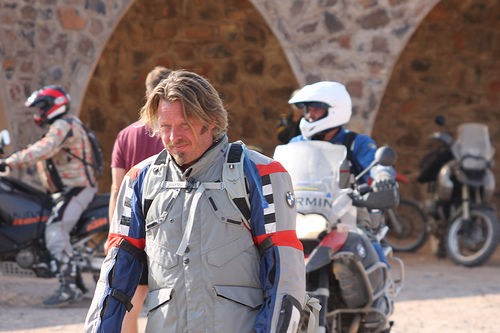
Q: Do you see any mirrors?
A: Yes, there is a mirror.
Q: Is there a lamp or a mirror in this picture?
A: Yes, there is a mirror.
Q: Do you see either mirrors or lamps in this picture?
A: Yes, there is a mirror.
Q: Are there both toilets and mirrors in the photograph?
A: No, there is a mirror but no toilets.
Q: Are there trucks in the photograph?
A: No, there are no trucks.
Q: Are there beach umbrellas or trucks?
A: No, there are no trucks or beach umbrellas.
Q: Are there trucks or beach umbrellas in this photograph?
A: No, there are no trucks or beach umbrellas.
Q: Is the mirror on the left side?
A: No, the mirror is on the right of the image.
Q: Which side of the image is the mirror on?
A: The mirror is on the right of the image.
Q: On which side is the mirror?
A: The mirror is on the right of the image.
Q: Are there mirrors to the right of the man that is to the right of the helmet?
A: Yes, there is a mirror to the right of the man.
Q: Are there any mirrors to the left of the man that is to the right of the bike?
A: No, the mirror is to the right of the man.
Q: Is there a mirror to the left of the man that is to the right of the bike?
A: No, the mirror is to the right of the man.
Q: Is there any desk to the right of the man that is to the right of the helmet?
A: No, there is a mirror to the right of the man.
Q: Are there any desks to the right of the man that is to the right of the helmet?
A: No, there is a mirror to the right of the man.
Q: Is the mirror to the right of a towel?
A: No, the mirror is to the right of the man.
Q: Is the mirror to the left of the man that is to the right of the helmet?
A: No, the mirror is to the right of the man.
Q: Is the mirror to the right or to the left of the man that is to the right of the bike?
A: The mirror is to the right of the man.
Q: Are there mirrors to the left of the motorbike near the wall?
A: Yes, there is a mirror to the left of the motorcycle.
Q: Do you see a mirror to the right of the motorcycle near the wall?
A: No, the mirror is to the left of the motorbike.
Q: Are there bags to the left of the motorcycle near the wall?
A: No, there is a mirror to the left of the motorcycle.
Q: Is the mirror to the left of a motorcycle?
A: Yes, the mirror is to the left of a motorcycle.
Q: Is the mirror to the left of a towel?
A: No, the mirror is to the left of a motorcycle.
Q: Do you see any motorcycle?
A: Yes, there is a motorcycle.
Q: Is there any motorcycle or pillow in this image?
A: Yes, there is a motorcycle.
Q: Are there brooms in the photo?
A: No, there are no brooms.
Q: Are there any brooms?
A: No, there are no brooms.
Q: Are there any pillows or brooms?
A: No, there are no brooms or pillows.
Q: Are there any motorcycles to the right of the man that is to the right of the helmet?
A: Yes, there is a motorcycle to the right of the man.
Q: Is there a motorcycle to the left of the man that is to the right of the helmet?
A: No, the motorcycle is to the right of the man.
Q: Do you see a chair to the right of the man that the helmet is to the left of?
A: No, there is a motorcycle to the right of the man.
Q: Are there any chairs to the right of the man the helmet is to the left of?
A: No, there is a motorcycle to the right of the man.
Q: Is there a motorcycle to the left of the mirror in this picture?
A: No, the motorcycle is to the right of the mirror.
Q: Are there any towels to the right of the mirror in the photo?
A: No, there is a motorcycle to the right of the mirror.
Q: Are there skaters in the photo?
A: No, there are no skaters.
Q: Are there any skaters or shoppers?
A: No, there are no skaters or shoppers.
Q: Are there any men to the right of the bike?
A: Yes, there is a man to the right of the bike.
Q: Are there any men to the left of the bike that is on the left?
A: No, the man is to the right of the bike.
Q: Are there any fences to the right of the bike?
A: No, there is a man to the right of the bike.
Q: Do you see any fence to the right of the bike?
A: No, there is a man to the right of the bike.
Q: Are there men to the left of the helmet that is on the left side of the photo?
A: No, the man is to the right of the helmet.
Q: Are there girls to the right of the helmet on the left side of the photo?
A: No, there is a man to the right of the helmet.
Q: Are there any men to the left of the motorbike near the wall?
A: Yes, there is a man to the left of the motorcycle.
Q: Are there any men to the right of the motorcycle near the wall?
A: No, the man is to the left of the motorbike.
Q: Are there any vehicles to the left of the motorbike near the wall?
A: No, there is a man to the left of the motorbike.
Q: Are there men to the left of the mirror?
A: Yes, there is a man to the left of the mirror.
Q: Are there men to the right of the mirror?
A: No, the man is to the left of the mirror.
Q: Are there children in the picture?
A: No, there are no children.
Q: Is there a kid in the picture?
A: No, there are no children.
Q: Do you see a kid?
A: No, there are no children.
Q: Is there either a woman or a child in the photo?
A: No, there are no children or women.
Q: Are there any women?
A: No, there are no women.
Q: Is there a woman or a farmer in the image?
A: No, there are no women or farmers.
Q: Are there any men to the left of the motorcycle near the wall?
A: Yes, there is a man to the left of the motorbike.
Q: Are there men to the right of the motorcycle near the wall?
A: No, the man is to the left of the motorbike.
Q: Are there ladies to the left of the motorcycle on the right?
A: No, there is a man to the left of the motorbike.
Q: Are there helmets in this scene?
A: Yes, there is a helmet.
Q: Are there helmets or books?
A: Yes, there is a helmet.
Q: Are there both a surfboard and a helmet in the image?
A: No, there is a helmet but no surfboards.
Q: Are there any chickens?
A: No, there are no chickens.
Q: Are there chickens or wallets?
A: No, there are no chickens or wallets.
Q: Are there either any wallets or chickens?
A: No, there are no chickens or wallets.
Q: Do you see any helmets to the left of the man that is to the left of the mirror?
A: Yes, there is a helmet to the left of the man.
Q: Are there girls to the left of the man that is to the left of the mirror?
A: No, there is a helmet to the left of the man.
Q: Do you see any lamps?
A: No, there are no lamps.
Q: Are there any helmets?
A: Yes, there is a helmet.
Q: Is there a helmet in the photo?
A: Yes, there is a helmet.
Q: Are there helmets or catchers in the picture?
A: Yes, there is a helmet.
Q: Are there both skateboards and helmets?
A: No, there is a helmet but no skateboards.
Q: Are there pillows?
A: No, there are no pillows.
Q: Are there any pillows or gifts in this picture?
A: No, there are no pillows or gifts.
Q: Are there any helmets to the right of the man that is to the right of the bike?
A: Yes, there is a helmet to the right of the man.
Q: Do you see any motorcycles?
A: Yes, there is a motorcycle.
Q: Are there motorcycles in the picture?
A: Yes, there is a motorcycle.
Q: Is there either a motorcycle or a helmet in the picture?
A: Yes, there is a motorcycle.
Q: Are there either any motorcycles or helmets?
A: Yes, there is a motorcycle.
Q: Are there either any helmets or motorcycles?
A: Yes, there is a motorcycle.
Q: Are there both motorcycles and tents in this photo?
A: No, there is a motorcycle but no tents.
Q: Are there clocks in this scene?
A: No, there are no clocks.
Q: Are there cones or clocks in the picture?
A: No, there are no clocks or cones.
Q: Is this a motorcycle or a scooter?
A: This is a motorcycle.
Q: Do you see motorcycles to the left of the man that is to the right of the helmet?
A: No, the motorcycle is to the right of the man.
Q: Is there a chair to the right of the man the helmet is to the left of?
A: No, there is a motorcycle to the right of the man.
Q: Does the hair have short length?
A: Yes, the hair is short.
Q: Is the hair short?
A: Yes, the hair is short.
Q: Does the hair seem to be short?
A: Yes, the hair is short.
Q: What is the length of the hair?
A: The hair is short.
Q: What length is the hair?
A: The hair is short.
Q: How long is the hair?
A: The hair is short.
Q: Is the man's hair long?
A: No, the hair is short.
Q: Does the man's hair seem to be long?
A: No, the hair is short.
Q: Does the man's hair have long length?
A: No, the hair is short.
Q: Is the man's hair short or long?
A: The hair is short.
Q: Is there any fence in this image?
A: No, there are no fences.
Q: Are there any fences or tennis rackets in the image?
A: No, there are no fences or tennis rackets.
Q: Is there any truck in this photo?
A: No, there are no trucks.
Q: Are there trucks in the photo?
A: No, there are no trucks.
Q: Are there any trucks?
A: No, there are no trucks.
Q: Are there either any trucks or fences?
A: No, there are no trucks or fences.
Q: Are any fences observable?
A: No, there are no fences.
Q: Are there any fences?
A: No, there are no fences.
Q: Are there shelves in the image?
A: No, there are no shelves.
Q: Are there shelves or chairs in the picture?
A: No, there are no shelves or chairs.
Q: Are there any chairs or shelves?
A: No, there are no shelves or chairs.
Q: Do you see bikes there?
A: Yes, there is a bike.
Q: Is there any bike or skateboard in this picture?
A: Yes, there is a bike.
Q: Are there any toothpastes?
A: No, there are no toothpastes.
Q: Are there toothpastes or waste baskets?
A: No, there are no toothpastes or waste baskets.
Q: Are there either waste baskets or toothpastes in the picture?
A: No, there are no toothpastes or waste baskets.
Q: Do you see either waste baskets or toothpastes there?
A: No, there are no toothpastes or waste baskets.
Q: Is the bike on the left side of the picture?
A: Yes, the bike is on the left of the image.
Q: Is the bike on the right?
A: No, the bike is on the left of the image.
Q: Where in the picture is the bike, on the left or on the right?
A: The bike is on the left of the image.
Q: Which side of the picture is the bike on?
A: The bike is on the left of the image.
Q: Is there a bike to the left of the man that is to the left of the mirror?
A: Yes, there is a bike to the left of the man.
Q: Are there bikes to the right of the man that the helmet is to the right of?
A: No, the bike is to the left of the man.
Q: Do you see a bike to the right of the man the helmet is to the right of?
A: No, the bike is to the left of the man.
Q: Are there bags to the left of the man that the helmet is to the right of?
A: No, there is a bike to the left of the man.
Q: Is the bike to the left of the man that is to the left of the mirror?
A: Yes, the bike is to the left of the man.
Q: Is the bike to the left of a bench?
A: No, the bike is to the left of the man.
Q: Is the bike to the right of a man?
A: No, the bike is to the left of a man.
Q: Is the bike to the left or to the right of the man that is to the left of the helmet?
A: The bike is to the left of the man.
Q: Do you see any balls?
A: No, there are no balls.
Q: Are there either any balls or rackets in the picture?
A: No, there are no balls or rackets.